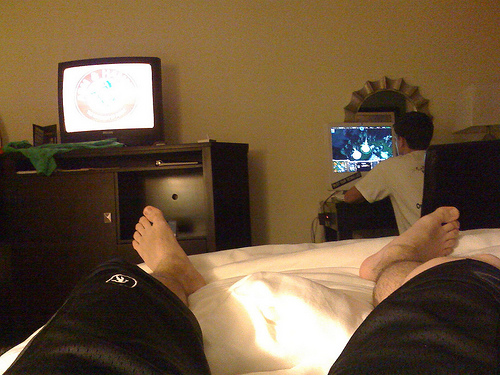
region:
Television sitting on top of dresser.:
[46, 48, 185, 151]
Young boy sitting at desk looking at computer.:
[347, 114, 464, 231]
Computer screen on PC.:
[321, 118, 407, 193]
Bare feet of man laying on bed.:
[127, 204, 482, 278]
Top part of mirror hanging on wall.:
[343, 65, 444, 120]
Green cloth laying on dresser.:
[3, 130, 128, 179]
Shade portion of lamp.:
[448, 77, 498, 141]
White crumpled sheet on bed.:
[208, 258, 351, 368]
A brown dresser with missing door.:
[6, 138, 248, 311]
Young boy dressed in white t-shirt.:
[351, 152, 440, 236]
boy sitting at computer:
[326, 113, 426, 235]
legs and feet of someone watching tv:
[31, 204, 498, 374]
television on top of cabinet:
[53, 54, 170, 145]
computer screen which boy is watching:
[319, 119, 406, 190]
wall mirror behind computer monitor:
[341, 70, 438, 128]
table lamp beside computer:
[449, 80, 499, 142]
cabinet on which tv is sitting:
[8, 142, 253, 303]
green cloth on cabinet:
[7, 135, 129, 180]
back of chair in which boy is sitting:
[423, 136, 498, 231]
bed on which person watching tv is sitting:
[16, 226, 499, 373]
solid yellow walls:
[210, 29, 318, 86]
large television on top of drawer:
[39, 48, 174, 149]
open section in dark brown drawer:
[139, 180, 239, 229]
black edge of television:
[143, 53, 195, 97]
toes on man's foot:
[124, 202, 174, 245]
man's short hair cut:
[388, 108, 443, 158]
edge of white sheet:
[248, 229, 328, 274]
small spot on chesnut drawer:
[73, 202, 126, 236]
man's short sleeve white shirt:
[323, 165, 415, 215]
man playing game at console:
[292, 108, 474, 223]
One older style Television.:
[42, 49, 171, 151]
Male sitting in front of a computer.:
[321, 102, 431, 219]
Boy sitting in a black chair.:
[329, 111, 478, 227]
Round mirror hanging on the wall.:
[338, 66, 437, 143]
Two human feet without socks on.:
[106, 197, 464, 285]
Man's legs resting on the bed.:
[75, 194, 492, 368]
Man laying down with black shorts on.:
[25, 241, 498, 356]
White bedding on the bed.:
[177, 222, 359, 373]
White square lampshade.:
[445, 75, 498, 142]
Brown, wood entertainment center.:
[0, 130, 255, 328]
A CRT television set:
[49, 51, 181, 129]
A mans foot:
[131, 196, 203, 286]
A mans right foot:
[351, 198, 464, 267]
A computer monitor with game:
[325, 116, 395, 166]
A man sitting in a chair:
[353, 124, 499, 222]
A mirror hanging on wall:
[347, 74, 412, 120]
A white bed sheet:
[209, 249, 334, 331]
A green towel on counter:
[8, 133, 118, 179]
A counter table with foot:
[8, 132, 239, 244]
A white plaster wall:
[213, 23, 322, 116]